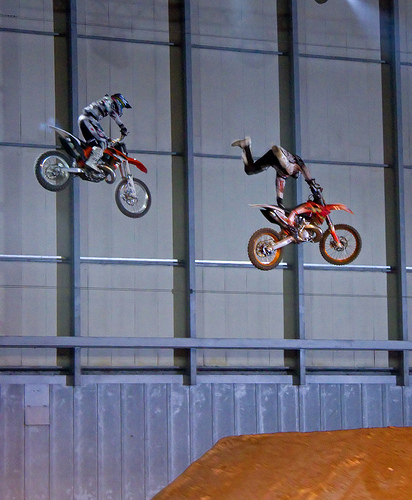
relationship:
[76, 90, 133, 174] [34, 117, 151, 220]
people riding bike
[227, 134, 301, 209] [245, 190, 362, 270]
people riding dirt bike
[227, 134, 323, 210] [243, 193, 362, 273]
people doing stunt on bike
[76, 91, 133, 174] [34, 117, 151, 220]
people doing stunt on bike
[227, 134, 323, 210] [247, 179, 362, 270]
people with motorcycle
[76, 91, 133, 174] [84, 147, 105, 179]
people with boots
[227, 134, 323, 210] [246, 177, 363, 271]
people on bike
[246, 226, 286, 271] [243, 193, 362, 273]
wheel on bike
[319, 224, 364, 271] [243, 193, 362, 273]
wheel on bike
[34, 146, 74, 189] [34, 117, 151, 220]
wheel on bike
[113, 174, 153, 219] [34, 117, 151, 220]
wheel on bike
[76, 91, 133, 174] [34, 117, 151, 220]
people on bike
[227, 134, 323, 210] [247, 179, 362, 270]
people on motorcycle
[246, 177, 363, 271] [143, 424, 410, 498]
bike over ramp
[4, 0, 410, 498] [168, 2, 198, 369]
building has rod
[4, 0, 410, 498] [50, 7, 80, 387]
building has rod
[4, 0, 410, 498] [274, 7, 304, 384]
building has rod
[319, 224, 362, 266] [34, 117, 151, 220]
wheel of bike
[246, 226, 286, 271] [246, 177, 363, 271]
wheel of bike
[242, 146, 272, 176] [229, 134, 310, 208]
leg of rider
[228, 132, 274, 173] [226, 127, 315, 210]
leg of rider